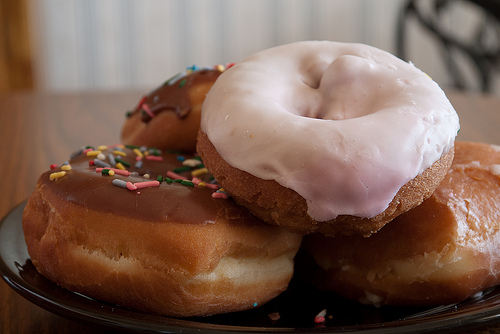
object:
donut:
[195, 39, 460, 237]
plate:
[3, 191, 500, 334]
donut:
[307, 138, 497, 306]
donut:
[23, 142, 305, 320]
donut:
[120, 69, 232, 153]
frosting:
[197, 39, 455, 222]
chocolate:
[141, 73, 193, 124]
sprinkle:
[140, 172, 154, 178]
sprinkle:
[81, 148, 94, 154]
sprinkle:
[180, 178, 196, 187]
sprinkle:
[47, 171, 67, 184]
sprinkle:
[142, 103, 155, 122]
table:
[2, 87, 500, 333]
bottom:
[20, 244, 303, 321]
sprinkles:
[179, 157, 203, 167]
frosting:
[39, 145, 256, 225]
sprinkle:
[108, 167, 134, 178]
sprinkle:
[211, 192, 226, 198]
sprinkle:
[87, 156, 115, 169]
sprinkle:
[316, 308, 328, 317]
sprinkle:
[327, 312, 334, 319]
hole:
[279, 79, 387, 121]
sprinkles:
[141, 103, 156, 117]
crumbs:
[268, 312, 281, 320]